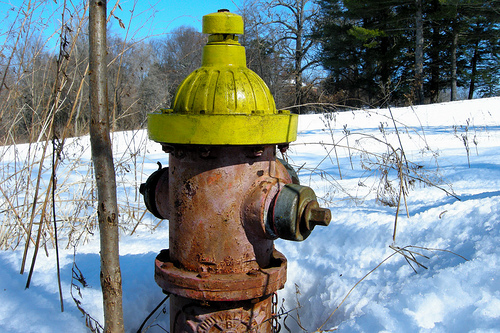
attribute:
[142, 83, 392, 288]
hydrant — brown, yellow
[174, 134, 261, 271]
hydrant — yellow, brown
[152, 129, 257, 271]
hydrant — brown, yellow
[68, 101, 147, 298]
tree — thin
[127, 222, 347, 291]
hydrant — brown, yellow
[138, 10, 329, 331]
fire hydrant — yellow, rusted, metallic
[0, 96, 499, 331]
snow — white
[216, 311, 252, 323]
word — Valve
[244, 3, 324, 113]
tree — bare branched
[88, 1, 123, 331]
tree — thin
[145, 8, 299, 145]
top — yellow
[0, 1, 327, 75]
sky — blue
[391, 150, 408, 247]
branch — brown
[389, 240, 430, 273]
branch — brown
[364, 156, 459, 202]
branch — brown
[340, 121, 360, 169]
branch — brown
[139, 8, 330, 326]
hydrant — red, yellow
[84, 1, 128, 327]
tree — thin